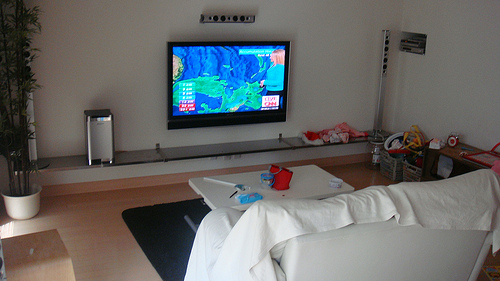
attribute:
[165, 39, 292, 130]
tv — flat, here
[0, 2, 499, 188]
wall — white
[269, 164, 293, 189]
bag — red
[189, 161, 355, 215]
table — white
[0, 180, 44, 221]
pot — white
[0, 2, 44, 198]
plant — tall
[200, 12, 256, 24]
speaker — small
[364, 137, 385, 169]
bucket — clear, glass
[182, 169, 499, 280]
cover — white, here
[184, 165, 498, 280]
couch — white, here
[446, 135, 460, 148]
alarm clock — red, small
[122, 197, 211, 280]
rug — black, here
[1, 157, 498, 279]
floor — wooden, here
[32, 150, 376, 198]
trim — wood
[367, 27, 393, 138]
speaker — tall